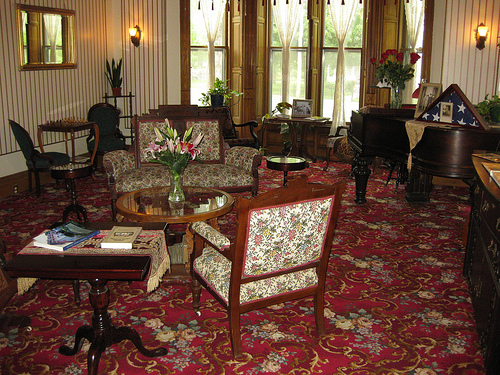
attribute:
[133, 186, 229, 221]
table — forefront, round, wood, glass, antique, coffee, wooden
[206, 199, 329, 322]
chair — beside, wood, trimmed, upholstered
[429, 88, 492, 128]
flag — veteran, framed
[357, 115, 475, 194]
piano — background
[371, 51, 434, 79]
roses — red, bouqet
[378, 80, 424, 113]
vase — clear, glass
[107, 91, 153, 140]
shelf — 3-tier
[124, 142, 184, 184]
couch — flowered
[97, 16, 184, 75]
light — on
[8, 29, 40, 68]
frame — gold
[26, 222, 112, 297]
wood — dark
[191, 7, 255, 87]
curtains — sheer, white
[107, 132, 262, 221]
seat — upholstered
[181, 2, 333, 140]
window — tall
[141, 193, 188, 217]
board — chess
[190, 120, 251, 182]
fabric — floral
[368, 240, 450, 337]
floor — red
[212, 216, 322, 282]
seats — white